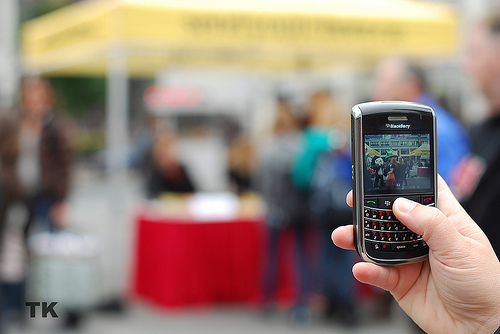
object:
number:
[371, 209, 376, 216]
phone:
[351, 101, 438, 266]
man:
[332, 172, 500, 333]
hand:
[331, 172, 500, 333]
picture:
[1, 0, 500, 332]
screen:
[365, 133, 430, 191]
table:
[136, 210, 376, 308]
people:
[127, 121, 210, 202]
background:
[0, 0, 499, 333]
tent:
[18, 0, 465, 299]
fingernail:
[397, 198, 416, 213]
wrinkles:
[448, 237, 477, 261]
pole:
[105, 46, 135, 301]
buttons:
[420, 194, 433, 204]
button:
[378, 197, 395, 210]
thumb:
[393, 196, 477, 255]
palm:
[397, 194, 486, 332]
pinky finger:
[351, 261, 399, 292]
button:
[363, 195, 380, 208]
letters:
[407, 124, 411, 130]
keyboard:
[364, 196, 436, 254]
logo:
[385, 122, 412, 130]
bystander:
[1, 74, 73, 325]